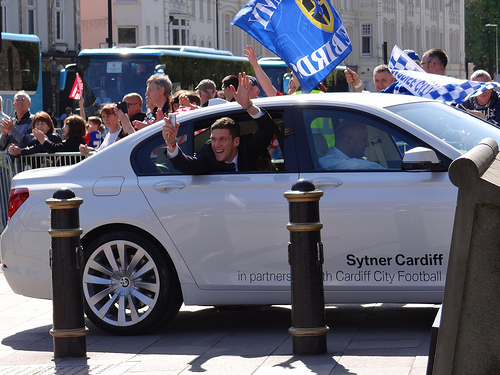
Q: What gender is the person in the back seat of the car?
A: Male.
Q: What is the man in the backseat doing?
A: Waving.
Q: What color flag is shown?
A: Blue.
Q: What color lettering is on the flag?
A: White.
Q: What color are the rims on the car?
A: Silver.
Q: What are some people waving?
A: Flags.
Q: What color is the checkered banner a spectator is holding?
A: Blue and white.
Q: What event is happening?
A: A parade.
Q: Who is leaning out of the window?
A: A man in a suit.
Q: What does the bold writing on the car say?
A: Sytner Cardiff.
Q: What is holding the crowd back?
A: A metal barricade.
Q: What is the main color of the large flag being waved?
A: Blue.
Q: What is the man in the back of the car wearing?
A: A suit.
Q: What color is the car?
A: White.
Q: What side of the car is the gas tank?
A: Passenger side.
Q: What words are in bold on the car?
A: Sytner Cardiff.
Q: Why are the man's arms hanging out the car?
A: He is waving.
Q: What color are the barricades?
A: Grey.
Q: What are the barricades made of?
A: Metal.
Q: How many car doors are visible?
A: 2.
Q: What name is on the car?
A: Sytner Cardiff.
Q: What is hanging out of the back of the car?
A: A man.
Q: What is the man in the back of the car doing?
A: Waving.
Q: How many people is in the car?
A: 2.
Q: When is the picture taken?
A: Daytime.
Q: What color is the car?
A: White.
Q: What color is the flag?
A: Blue.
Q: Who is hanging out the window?
A: A man.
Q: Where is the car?
A: On a street.